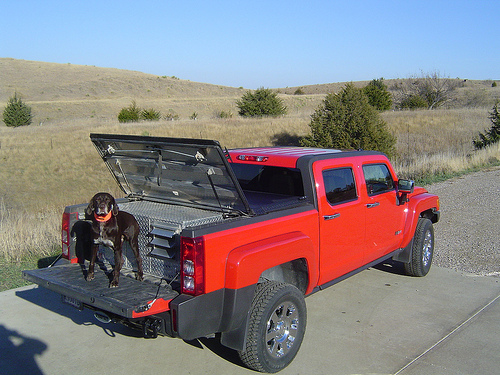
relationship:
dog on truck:
[64, 188, 156, 286] [55, 114, 427, 371]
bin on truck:
[96, 197, 218, 288] [20, 131, 442, 375]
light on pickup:
[164, 231, 222, 305] [40, 118, 425, 368]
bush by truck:
[5, 90, 40, 123] [88, 147, 409, 327]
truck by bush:
[113, 147, 486, 362] [105, 100, 185, 139]